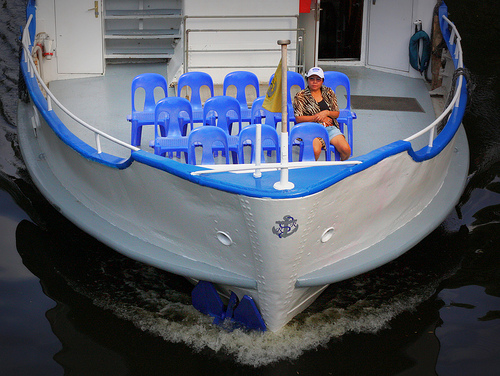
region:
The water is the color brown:
[13, 240, 128, 356]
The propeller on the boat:
[184, 280, 281, 347]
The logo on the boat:
[268, 213, 305, 240]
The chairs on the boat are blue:
[126, 67, 362, 157]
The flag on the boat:
[261, 26, 296, 183]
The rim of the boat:
[14, 18, 492, 215]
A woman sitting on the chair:
[287, 67, 359, 162]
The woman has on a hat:
[297, 60, 337, 91]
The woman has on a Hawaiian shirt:
[294, 89, 345, 116]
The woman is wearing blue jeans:
[313, 122, 346, 139]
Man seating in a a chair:
[276, 72, 360, 162]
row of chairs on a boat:
[138, 105, 439, 162]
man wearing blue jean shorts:
[295, 120, 350, 143]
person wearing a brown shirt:
[293, 93, 338, 115]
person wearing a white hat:
[303, 59, 336, 75]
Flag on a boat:
[243, 44, 330, 141]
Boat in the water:
[67, 107, 447, 368]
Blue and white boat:
[116, 159, 477, 260]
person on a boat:
[273, 84, 371, 181]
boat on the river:
[68, 143, 388, 302]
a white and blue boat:
[14, 0, 475, 334]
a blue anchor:
[189, 280, 264, 335]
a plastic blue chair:
[187, 127, 229, 168]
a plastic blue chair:
[235, 123, 279, 166]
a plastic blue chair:
[288, 123, 330, 162]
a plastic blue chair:
[317, 68, 354, 153]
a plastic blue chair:
[267, 69, 307, 134]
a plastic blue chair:
[220, 68, 260, 133]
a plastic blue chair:
[175, 71, 215, 133]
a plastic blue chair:
[130, 73, 168, 143]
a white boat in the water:
[14, 3, 488, 355]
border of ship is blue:
[11, 15, 475, 223]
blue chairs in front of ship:
[123, 58, 362, 190]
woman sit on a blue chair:
[293, 63, 349, 160]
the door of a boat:
[313, 2, 370, 69]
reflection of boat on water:
[13, 268, 483, 374]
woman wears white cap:
[293, 63, 344, 128]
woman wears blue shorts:
[293, 66, 355, 165]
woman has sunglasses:
[290, 54, 353, 164]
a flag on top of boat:
[253, 30, 315, 202]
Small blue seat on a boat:
[130, 66, 170, 142]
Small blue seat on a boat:
[178, 65, 220, 130]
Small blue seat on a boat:
[220, 69, 258, 134]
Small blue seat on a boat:
[151, 94, 193, 144]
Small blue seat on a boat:
[195, 94, 246, 151]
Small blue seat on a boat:
[181, 122, 236, 187]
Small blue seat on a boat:
[236, 124, 282, 173]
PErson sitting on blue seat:
[296, 66, 357, 159]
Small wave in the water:
[50, 256, 438, 356]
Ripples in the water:
[18, 239, 430, 371]